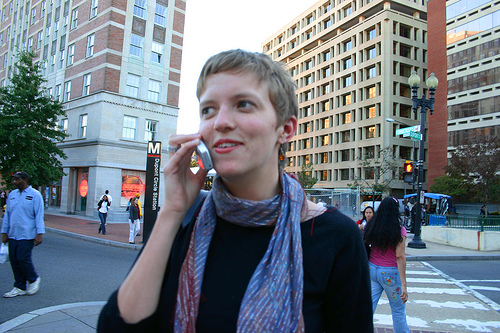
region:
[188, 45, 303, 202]
a girl with short hair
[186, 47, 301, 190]
a lady on the phone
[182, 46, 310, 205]
a girl on the phone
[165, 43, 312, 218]
a girl using her cell phone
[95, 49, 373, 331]
a lady with a scarf around her neck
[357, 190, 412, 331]
a woman with long hair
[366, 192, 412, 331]
a woman in a pink shirt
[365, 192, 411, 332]
a woman in a crosswalk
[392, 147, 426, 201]
a walk, don't walk signal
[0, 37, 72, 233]
a tree in the city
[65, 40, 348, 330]
this is a woman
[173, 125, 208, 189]
the womans right hand is holding a cell phone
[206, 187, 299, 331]
the woman has a scarf on his neck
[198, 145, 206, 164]
the cell phone is grey in color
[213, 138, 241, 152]
the mouth has red lipstick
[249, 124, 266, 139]
the woman is light skinned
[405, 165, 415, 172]
the traffic light is amber in color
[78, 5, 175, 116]
the building is tall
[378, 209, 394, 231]
the woman has long hair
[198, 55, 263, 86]
the woman has short hair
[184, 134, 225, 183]
Cell phone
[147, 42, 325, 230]
Girl on cell phone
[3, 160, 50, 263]
Man walking in the background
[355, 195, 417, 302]
Woman in pink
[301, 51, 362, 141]
Building windows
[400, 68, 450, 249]
Street lamp with many signs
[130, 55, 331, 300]
Young woman talking on a cell phone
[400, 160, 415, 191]
Don't walk sign alerting road crossers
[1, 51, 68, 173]
A tree downtown in a crowded area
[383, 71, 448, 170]
Street signs from a street lamp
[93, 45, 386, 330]
woman talking on cell phone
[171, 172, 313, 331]
scarf around woman's neck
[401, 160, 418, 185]
traffic light indicating not to walk across street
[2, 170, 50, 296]
man walking in street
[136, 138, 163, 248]
sign for subway station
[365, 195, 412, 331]
woman in pink shirt walking across street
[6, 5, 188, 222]
large building on corner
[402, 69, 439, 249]
double globe street light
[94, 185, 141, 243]
people walking on sidewalk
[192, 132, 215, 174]
cell phone in woman's hand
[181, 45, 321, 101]
Short blonde haired woman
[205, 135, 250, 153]
Red lipstick on woman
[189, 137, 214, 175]
Silver phone in hand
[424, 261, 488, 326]
Crosswalk in middle of street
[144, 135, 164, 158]
Capital M on pole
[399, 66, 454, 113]
Lamps on top of pole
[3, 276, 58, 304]
Pair of white tennis shoes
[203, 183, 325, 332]
Blue print scarf around neck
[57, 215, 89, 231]
Brick sidewalk along street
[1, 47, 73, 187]
Tall green pine tree